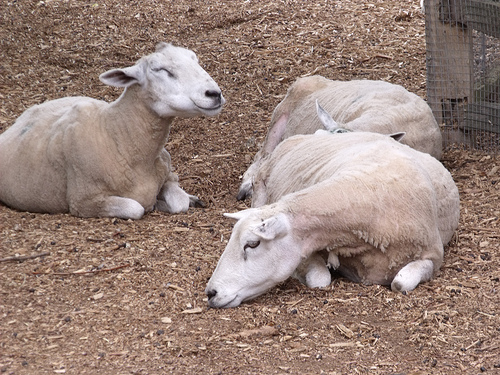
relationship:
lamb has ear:
[2, 39, 227, 224] [92, 63, 140, 88]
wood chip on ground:
[125, 243, 130, 248] [3, 1, 500, 375]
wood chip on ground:
[122, 242, 134, 257] [2, 0, 444, 371]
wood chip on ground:
[125, 243, 130, 248] [2, 0, 444, 371]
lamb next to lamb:
[2, 39, 227, 224] [209, 132, 463, 298]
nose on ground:
[204, 87, 219, 99] [2, 0, 444, 371]